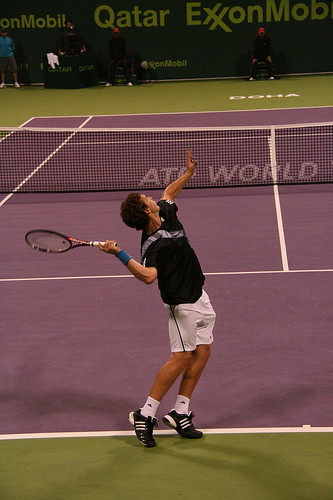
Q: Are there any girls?
A: No, there are no girls.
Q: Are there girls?
A: No, there are no girls.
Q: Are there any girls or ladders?
A: No, there are no girls or ladders.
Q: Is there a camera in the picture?
A: Yes, there is a camera.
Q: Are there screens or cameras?
A: Yes, there is a camera.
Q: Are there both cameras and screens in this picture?
A: No, there is a camera but no screens.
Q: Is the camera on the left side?
A: Yes, the camera is on the left of the image.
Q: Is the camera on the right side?
A: No, the camera is on the left of the image.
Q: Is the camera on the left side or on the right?
A: The camera is on the left of the image.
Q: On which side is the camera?
A: The camera is on the left of the image.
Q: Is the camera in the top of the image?
A: Yes, the camera is in the top of the image.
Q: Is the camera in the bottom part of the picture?
A: No, the camera is in the top of the image.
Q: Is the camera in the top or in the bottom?
A: The camera is in the top of the image.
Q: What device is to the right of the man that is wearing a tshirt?
A: The device is a camera.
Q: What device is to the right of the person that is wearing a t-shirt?
A: The device is a camera.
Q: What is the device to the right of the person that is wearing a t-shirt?
A: The device is a camera.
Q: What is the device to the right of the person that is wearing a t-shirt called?
A: The device is a camera.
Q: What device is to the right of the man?
A: The device is a camera.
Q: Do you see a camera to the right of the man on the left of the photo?
A: Yes, there is a camera to the right of the man.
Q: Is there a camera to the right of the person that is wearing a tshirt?
A: Yes, there is a camera to the right of the man.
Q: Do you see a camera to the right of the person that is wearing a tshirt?
A: Yes, there is a camera to the right of the man.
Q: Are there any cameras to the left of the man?
A: No, the camera is to the right of the man.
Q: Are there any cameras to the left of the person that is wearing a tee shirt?
A: No, the camera is to the right of the man.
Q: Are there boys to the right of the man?
A: No, there is a camera to the right of the man.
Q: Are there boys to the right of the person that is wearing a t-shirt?
A: No, there is a camera to the right of the man.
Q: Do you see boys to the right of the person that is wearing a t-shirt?
A: No, there is a camera to the right of the man.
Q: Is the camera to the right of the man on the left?
A: Yes, the camera is to the right of the man.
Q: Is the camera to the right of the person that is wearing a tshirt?
A: Yes, the camera is to the right of the man.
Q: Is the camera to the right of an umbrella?
A: No, the camera is to the right of the man.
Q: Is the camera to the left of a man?
A: No, the camera is to the right of a man.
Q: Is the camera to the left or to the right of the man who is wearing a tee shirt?
A: The camera is to the right of the man.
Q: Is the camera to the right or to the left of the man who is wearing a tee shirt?
A: The camera is to the right of the man.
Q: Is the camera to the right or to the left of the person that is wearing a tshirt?
A: The camera is to the right of the man.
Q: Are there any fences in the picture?
A: No, there are no fences.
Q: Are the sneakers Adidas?
A: Yes, the sneakers are adidas.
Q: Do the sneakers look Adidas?
A: Yes, the sneakers are adidas.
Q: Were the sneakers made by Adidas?
A: Yes, the sneakers were made by adidas.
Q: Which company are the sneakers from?
A: The sneakers are from adidas.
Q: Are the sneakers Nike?
A: No, the sneakers are adidas.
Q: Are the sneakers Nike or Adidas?
A: The sneakers are adidas.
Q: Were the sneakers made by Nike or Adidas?
A: The sneakers were made adidas.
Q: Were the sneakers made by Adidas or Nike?
A: The sneakers were made adidas.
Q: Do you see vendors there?
A: No, there are no vendors.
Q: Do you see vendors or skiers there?
A: No, there are no vendors or skiers.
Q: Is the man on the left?
A: Yes, the man is on the left of the image.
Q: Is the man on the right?
A: No, the man is on the left of the image.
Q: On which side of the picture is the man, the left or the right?
A: The man is on the left of the image.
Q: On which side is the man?
A: The man is on the left of the image.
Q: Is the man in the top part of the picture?
A: Yes, the man is in the top of the image.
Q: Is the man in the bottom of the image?
A: No, the man is in the top of the image.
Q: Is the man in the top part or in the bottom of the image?
A: The man is in the top of the image.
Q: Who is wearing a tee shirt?
A: The man is wearing a tee shirt.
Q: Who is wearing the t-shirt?
A: The man is wearing a tee shirt.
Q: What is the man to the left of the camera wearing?
A: The man is wearing a tee shirt.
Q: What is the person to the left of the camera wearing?
A: The man is wearing a tee shirt.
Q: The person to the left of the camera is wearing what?
A: The man is wearing a tee shirt.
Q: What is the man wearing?
A: The man is wearing a tee shirt.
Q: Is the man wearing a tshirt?
A: Yes, the man is wearing a tshirt.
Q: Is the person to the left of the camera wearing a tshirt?
A: Yes, the man is wearing a tshirt.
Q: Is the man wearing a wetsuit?
A: No, the man is wearing a tshirt.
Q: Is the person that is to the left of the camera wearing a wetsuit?
A: No, the man is wearing a tshirt.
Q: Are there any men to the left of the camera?
A: Yes, there is a man to the left of the camera.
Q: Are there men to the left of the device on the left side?
A: Yes, there is a man to the left of the camera.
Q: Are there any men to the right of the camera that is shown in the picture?
A: No, the man is to the left of the camera.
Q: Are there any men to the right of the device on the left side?
A: No, the man is to the left of the camera.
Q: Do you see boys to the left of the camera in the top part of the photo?
A: No, there is a man to the left of the camera.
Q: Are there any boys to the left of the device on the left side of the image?
A: No, there is a man to the left of the camera.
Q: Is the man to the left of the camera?
A: Yes, the man is to the left of the camera.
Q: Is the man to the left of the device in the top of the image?
A: Yes, the man is to the left of the camera.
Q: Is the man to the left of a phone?
A: No, the man is to the left of the camera.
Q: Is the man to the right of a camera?
A: No, the man is to the left of a camera.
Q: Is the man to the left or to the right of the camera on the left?
A: The man is to the left of the camera.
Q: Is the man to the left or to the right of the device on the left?
A: The man is to the left of the camera.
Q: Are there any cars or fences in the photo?
A: No, there are no fences or cars.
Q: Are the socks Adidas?
A: Yes, the socks are adidas.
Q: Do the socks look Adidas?
A: Yes, the socks are adidas.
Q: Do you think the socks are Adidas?
A: Yes, the socks are adidas.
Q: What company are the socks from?
A: The socks are from adidas.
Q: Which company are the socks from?
A: The socks are from adidas.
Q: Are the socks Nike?
A: No, the socks are adidas.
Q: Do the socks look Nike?
A: No, the socks are adidas.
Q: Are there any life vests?
A: No, there are no life vests.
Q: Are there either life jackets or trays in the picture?
A: No, there are no life jackets or trays.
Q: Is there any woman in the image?
A: No, there are no women.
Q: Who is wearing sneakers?
A: The player is wearing sneakers.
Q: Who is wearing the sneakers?
A: The player is wearing sneakers.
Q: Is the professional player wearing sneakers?
A: Yes, the player is wearing sneakers.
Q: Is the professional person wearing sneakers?
A: Yes, the player is wearing sneakers.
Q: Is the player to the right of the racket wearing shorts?
A: No, the player is wearing sneakers.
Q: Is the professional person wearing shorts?
A: No, the player is wearing sneakers.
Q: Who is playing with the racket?
A: The player is playing with the racket.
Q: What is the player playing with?
A: The player is playing with a racket.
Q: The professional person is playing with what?
A: The player is playing with a racket.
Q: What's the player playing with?
A: The player is playing with a racket.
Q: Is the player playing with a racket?
A: Yes, the player is playing with a racket.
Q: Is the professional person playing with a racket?
A: Yes, the player is playing with a racket.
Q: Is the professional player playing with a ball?
A: No, the player is playing with a racket.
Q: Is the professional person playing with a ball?
A: No, the player is playing with a racket.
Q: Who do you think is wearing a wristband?
A: The player is wearing a wristband.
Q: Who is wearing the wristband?
A: The player is wearing a wristband.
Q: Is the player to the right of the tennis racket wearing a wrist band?
A: Yes, the player is wearing a wrist band.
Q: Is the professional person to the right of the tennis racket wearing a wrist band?
A: Yes, the player is wearing a wrist band.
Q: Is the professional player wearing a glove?
A: No, the player is wearing a wrist band.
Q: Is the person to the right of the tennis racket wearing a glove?
A: No, the player is wearing a wrist band.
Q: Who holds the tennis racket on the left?
A: The player holds the racket.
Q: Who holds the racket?
A: The player holds the racket.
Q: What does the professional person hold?
A: The player holds the racket.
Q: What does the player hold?
A: The player holds the racket.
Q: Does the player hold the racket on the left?
A: Yes, the player holds the racket.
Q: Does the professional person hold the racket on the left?
A: Yes, the player holds the racket.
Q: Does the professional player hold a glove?
A: No, the player holds the racket.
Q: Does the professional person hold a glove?
A: No, the player holds the racket.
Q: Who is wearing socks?
A: The player is wearing socks.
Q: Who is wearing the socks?
A: The player is wearing socks.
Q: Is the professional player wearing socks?
A: Yes, the player is wearing socks.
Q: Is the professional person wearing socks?
A: Yes, the player is wearing socks.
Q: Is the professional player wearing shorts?
A: No, the player is wearing socks.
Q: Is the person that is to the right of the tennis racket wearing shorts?
A: No, the player is wearing socks.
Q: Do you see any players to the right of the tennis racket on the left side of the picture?
A: Yes, there is a player to the right of the racket.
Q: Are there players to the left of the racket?
A: No, the player is to the right of the racket.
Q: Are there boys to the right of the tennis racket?
A: No, there is a player to the right of the tennis racket.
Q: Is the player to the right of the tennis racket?
A: Yes, the player is to the right of the tennis racket.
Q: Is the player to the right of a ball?
A: No, the player is to the right of the tennis racket.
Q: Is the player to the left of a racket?
A: No, the player is to the right of a racket.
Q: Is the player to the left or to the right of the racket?
A: The player is to the right of the racket.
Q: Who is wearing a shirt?
A: The player is wearing a shirt.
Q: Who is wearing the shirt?
A: The player is wearing a shirt.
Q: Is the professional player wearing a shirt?
A: Yes, the player is wearing a shirt.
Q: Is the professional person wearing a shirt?
A: Yes, the player is wearing a shirt.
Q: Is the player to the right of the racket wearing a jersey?
A: No, the player is wearing a shirt.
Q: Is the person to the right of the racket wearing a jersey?
A: No, the player is wearing a shirt.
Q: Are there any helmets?
A: No, there are no helmets.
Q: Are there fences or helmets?
A: No, there are no helmets or fences.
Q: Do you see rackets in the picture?
A: Yes, there is a racket.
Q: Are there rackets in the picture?
A: Yes, there is a racket.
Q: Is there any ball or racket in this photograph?
A: Yes, there is a racket.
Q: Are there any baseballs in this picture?
A: No, there are no baseballs.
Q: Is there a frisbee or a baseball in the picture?
A: No, there are no baseballs or frisbees.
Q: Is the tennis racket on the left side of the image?
A: Yes, the tennis racket is on the left of the image.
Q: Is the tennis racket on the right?
A: No, the tennis racket is on the left of the image.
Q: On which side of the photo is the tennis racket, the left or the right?
A: The tennis racket is on the left of the image.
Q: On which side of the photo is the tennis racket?
A: The tennis racket is on the left of the image.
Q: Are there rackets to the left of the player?
A: Yes, there is a racket to the left of the player.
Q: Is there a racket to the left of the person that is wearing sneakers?
A: Yes, there is a racket to the left of the player.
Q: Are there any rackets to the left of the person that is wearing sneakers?
A: Yes, there is a racket to the left of the player.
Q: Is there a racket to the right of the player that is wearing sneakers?
A: No, the racket is to the left of the player.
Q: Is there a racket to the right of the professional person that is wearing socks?
A: No, the racket is to the left of the player.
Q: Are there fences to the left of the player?
A: No, there is a racket to the left of the player.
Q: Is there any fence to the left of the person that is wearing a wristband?
A: No, there is a racket to the left of the player.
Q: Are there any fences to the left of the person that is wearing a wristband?
A: No, there is a racket to the left of the player.